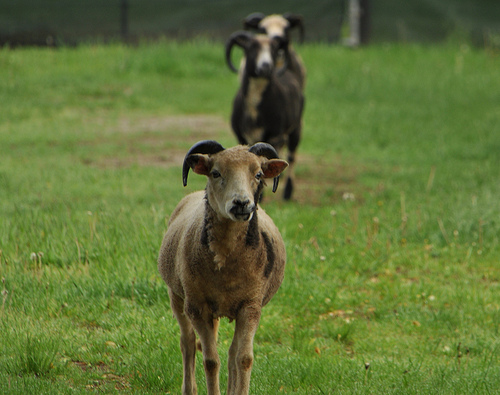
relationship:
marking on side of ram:
[250, 219, 293, 295] [161, 130, 373, 368]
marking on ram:
[244, 30, 272, 147] [224, 28, 306, 215]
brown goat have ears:
[221, 25, 308, 201] [261, 157, 288, 182]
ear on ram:
[259, 153, 289, 181] [149, 133, 289, 393]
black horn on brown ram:
[181, 138, 224, 185] [157, 138, 288, 394]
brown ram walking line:
[157, 138, 288, 394] [148, 10, 323, 393]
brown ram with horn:
[147, 132, 323, 392] [243, 135, 294, 200]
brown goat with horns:
[221, 25, 308, 201] [170, 132, 293, 191]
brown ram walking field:
[157, 138, 288, 394] [307, 72, 492, 387]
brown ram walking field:
[157, 138, 288, 394] [1, 44, 498, 394]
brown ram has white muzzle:
[157, 138, 288, 394] [218, 170, 254, 220]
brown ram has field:
[157, 138, 288, 394] [1, 44, 498, 394]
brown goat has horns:
[221, 25, 308, 201] [183, 137, 280, 191]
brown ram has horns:
[157, 138, 288, 394] [224, 30, 292, 77]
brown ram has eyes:
[157, 138, 288, 394] [201, 161, 278, 185]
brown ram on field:
[157, 138, 288, 394] [1, 44, 498, 394]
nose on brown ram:
[233, 197, 253, 207] [157, 138, 288, 394]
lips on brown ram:
[225, 205, 253, 223] [157, 138, 288, 394]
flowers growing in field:
[0, 46, 495, 390] [1, 44, 498, 394]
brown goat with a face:
[216, 20, 323, 202] [242, 35, 282, 76]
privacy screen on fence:
[0, 0, 500, 50] [3, 0, 498, 44]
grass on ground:
[355, 179, 459, 317] [4, 41, 496, 391]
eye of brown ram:
[255, 171, 266, 183] [157, 138, 288, 394]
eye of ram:
[208, 167, 224, 180] [149, 133, 289, 393]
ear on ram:
[186, 152, 215, 172] [149, 133, 289, 393]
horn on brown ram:
[238, 135, 313, 185] [157, 138, 288, 394]